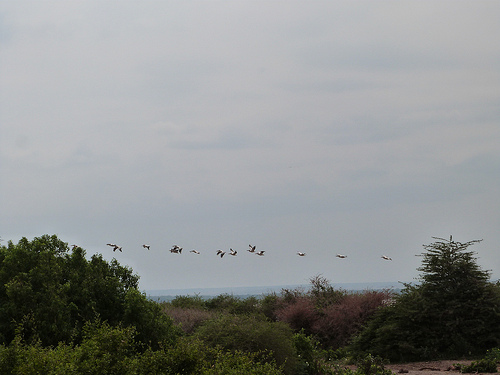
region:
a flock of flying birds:
[106, 239, 402, 270]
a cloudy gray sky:
[3, 2, 495, 219]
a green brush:
[1, 237, 166, 374]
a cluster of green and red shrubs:
[8, 265, 496, 374]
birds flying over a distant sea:
[101, 235, 419, 299]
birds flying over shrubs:
[29, 235, 469, 373]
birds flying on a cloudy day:
[98, 208, 407, 270]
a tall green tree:
[383, 238, 493, 374]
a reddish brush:
[281, 284, 376, 346]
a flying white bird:
[105, 240, 123, 252]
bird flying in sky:
[102, 238, 125, 259]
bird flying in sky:
[139, 240, 152, 250]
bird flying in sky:
[165, 241, 185, 255]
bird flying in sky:
[183, 245, 201, 260]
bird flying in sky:
[211, 244, 226, 259]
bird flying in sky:
[225, 243, 240, 257]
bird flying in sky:
[246, 238, 258, 254]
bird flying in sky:
[251, 246, 267, 258]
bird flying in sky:
[294, 247, 307, 259]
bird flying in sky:
[331, 249, 348, 263]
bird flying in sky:
[187, 245, 202, 255]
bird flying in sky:
[214, 247, 224, 258]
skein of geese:
[92, 221, 414, 268]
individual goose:
[103, 239, 126, 254]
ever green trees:
[357, 233, 493, 360]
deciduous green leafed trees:
[2, 228, 167, 328]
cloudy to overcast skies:
[6, 12, 488, 217]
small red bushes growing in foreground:
[276, 276, 394, 344]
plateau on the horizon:
[140, 272, 435, 308]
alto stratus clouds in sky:
[10, 15, 486, 212]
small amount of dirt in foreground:
[355, 356, 485, 372]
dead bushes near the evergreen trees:
[274, 281, 386, 336]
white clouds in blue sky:
[40, 35, 114, 115]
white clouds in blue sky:
[308, 82, 406, 140]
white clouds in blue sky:
[245, 58, 303, 128]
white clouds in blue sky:
[91, 15, 175, 73]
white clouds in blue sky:
[402, 38, 482, 113]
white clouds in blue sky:
[190, 91, 237, 152]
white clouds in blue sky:
[257, 135, 337, 213]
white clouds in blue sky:
[327, 199, 387, 270]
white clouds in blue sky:
[60, 86, 127, 144]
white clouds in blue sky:
[150, 52, 217, 99]